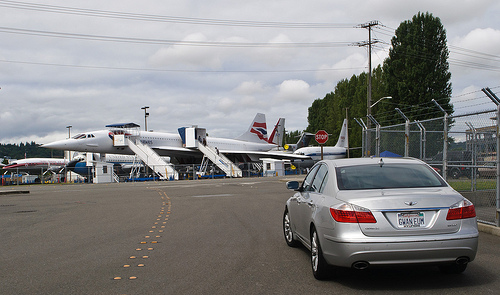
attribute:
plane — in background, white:
[6, 158, 67, 177]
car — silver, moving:
[281, 155, 481, 280]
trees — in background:
[306, 14, 447, 167]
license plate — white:
[394, 213, 431, 231]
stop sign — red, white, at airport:
[315, 129, 329, 143]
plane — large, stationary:
[53, 112, 284, 181]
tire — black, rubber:
[310, 231, 333, 280]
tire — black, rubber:
[283, 210, 297, 249]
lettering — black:
[399, 217, 425, 228]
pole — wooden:
[358, 20, 380, 158]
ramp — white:
[124, 138, 180, 181]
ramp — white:
[198, 143, 241, 176]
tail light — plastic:
[333, 212, 375, 225]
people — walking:
[195, 136, 235, 176]